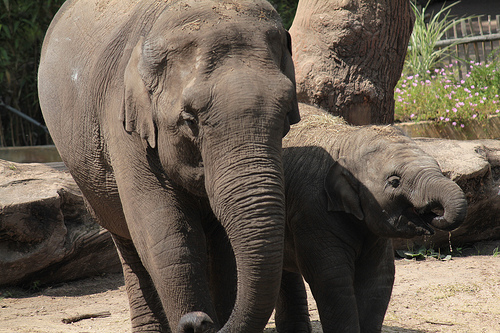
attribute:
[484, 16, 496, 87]
post — wood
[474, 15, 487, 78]
post — wood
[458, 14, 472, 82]
post — wood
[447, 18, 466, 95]
post — wood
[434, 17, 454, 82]
post — wood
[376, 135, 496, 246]
wall — cement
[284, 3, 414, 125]
trunk — tree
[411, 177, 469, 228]
trunk — curled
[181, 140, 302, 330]
trunk — curled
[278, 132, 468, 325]
elephant — baby, small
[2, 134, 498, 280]
wall — stone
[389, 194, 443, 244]
mouth — open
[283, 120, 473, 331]
elephant — small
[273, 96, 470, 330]
elephant — small, young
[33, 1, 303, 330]
elephant — adult, large, walking, larger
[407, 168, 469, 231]
trunk — bent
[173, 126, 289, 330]
trunk — hanging, swinging, very wrinkled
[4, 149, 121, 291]
rock — large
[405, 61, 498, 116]
wildflowers — pink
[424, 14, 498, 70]
fence — wooden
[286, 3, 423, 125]
tree trunk — large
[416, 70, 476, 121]
flowers — pink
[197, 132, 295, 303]
trunk — large, adult, elephant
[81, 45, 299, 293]
elephant — older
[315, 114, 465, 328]
elephant — baby